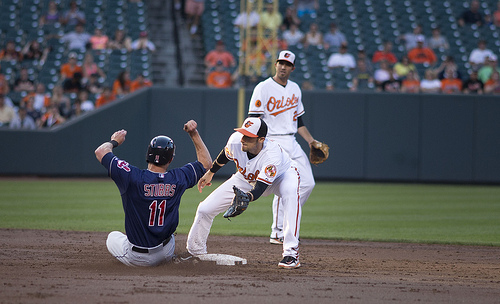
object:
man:
[168, 117, 300, 270]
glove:
[221, 185, 250, 218]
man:
[246, 47, 330, 247]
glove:
[308, 139, 327, 166]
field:
[0, 175, 499, 303]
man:
[93, 116, 211, 269]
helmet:
[145, 134, 174, 167]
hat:
[231, 117, 266, 139]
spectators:
[59, 25, 87, 51]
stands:
[0, 0, 500, 186]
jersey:
[247, 76, 306, 134]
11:
[148, 198, 166, 226]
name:
[143, 182, 178, 196]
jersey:
[110, 155, 207, 246]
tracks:
[340, 260, 399, 296]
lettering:
[263, 93, 298, 115]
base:
[197, 252, 247, 266]